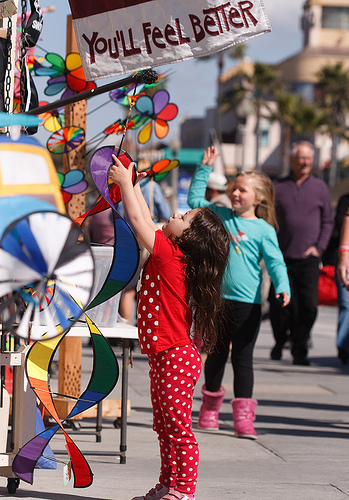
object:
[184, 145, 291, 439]
smiling woman